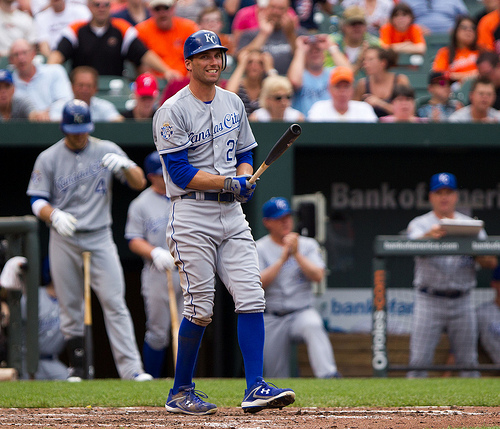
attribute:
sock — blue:
[170, 316, 204, 391]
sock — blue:
[235, 312, 266, 390]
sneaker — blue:
[159, 384, 216, 413]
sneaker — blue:
[239, 377, 302, 410]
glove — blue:
[218, 172, 254, 199]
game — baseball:
[8, 121, 493, 424]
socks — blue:
[172, 315, 280, 384]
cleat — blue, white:
[240, 375, 294, 411]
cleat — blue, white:
[162, 386, 218, 418]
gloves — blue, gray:
[237, 180, 257, 201]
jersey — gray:
[142, 77, 258, 197]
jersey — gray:
[27, 133, 132, 238]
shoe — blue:
[238, 382, 292, 414]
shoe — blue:
[158, 382, 216, 412]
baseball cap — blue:
[184, 33, 220, 63]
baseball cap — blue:
[427, 168, 463, 191]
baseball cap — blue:
[58, 86, 92, 131]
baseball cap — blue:
[142, 153, 165, 173]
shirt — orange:
[381, 21, 426, 48]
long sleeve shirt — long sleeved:
[155, 89, 258, 191]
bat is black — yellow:
[265, 125, 299, 165]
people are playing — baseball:
[23, 27, 483, 402]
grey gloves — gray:
[220, 175, 263, 206]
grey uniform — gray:
[150, 83, 287, 319]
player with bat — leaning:
[238, 115, 302, 193]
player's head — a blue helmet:
[177, 28, 240, 84]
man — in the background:
[42, 3, 180, 86]